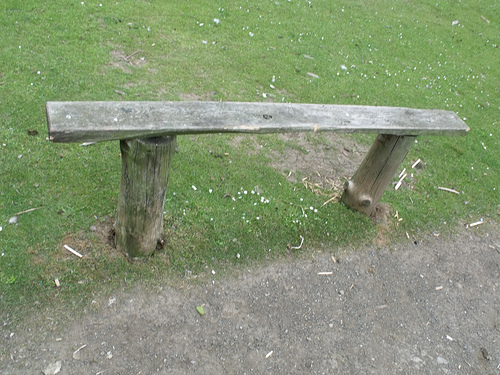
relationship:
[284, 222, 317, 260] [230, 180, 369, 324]
litter on ground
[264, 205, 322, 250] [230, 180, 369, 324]
twig on ground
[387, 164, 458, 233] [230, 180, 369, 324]
leaf on ground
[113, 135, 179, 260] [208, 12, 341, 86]
stump in grass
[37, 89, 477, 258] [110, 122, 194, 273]
bench has stump